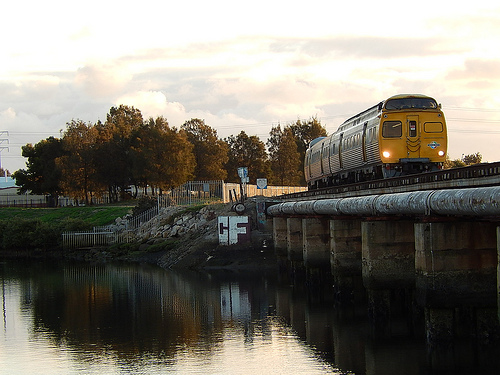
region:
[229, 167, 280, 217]
four signs in the shot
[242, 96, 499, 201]
train on the tracks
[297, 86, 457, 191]
train is yellow and black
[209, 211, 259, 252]
wall is spraypainted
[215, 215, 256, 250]
spraypaint is white and red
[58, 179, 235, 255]
metal fence with bars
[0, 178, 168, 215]
building in the background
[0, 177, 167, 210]
building is ehite tan and red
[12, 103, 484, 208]
trees leaves are brown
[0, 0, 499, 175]
sky is blue and cloudy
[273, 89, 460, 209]
A yellow train on a track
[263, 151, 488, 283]
Railroad track on bridge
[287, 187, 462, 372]
Bridge is over water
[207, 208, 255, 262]
CF painted near the water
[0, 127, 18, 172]
Power poles in the distance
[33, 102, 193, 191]
Trees against a cloudy sky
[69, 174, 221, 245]
A fence down to the water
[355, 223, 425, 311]
Under a bridge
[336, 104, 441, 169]
A yellow train car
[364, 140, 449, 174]
Lights on the train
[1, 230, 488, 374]
THE WATER IS CALM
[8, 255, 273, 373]
THE WATER IS REFLECTING THE TREES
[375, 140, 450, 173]
THE LIGHTS ARE ON THE TRAIN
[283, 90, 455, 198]
THE TRAIN IS YELLOW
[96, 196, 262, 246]
THE ROCKS ARE ON THE SHORE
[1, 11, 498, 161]
THE CLOUDS ARE PUFFY AND PINK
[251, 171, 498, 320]
THIS IS A BRIDGE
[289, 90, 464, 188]
THIS IS A TRAIN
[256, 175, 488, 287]
THE TRAIN IS ON THE BRIDGE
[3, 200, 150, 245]
THE RIVERBANK IS GREEN AND GRASSY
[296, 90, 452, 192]
The train driving on the tracks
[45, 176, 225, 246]
The gate separating the water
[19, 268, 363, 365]
The lake water is black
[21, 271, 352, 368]
The lake water is calm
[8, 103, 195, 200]
The trees in the park are green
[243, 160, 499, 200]
The train tracks on the cement structure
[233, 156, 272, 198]
The driving signs for the train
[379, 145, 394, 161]
The head light on the train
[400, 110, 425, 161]
The door for the train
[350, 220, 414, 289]
The cement column holding up the structure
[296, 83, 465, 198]
uncommon small yellow train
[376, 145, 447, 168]
two shining headlamps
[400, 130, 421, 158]
three chains make a door ladder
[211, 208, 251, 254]
'cf' graffiti above the river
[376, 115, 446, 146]
a squarish window, an oblongish window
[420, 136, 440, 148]
a blue+white logo w/ illegible print @ this distance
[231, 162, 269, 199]
several street signs, also too far to read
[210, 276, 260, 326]
tag's reflection in the water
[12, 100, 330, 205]
dark trees turning below a pale clouded sky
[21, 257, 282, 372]
the tree+sky reflections in the calm rippled water